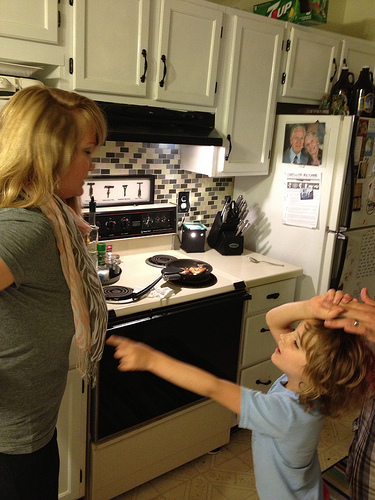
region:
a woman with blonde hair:
[0, 68, 110, 214]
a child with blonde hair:
[261, 293, 372, 423]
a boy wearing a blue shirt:
[251, 283, 361, 492]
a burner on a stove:
[142, 250, 180, 271]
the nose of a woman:
[84, 160, 97, 172]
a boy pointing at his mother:
[105, 283, 369, 413]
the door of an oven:
[93, 292, 253, 426]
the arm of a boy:
[105, 335, 243, 408]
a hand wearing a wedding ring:
[346, 288, 374, 338]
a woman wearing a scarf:
[4, 83, 116, 391]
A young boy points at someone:
[110, 287, 370, 498]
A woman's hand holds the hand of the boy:
[324, 288, 374, 342]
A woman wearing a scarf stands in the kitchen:
[0, 86, 108, 495]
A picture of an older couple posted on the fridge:
[282, 120, 325, 166]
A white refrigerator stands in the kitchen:
[279, 108, 372, 293]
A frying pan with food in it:
[164, 258, 211, 285]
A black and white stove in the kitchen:
[77, 209, 239, 497]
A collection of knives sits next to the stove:
[215, 196, 247, 255]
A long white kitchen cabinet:
[226, 14, 283, 173]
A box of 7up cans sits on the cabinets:
[250, 0, 325, 27]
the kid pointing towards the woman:
[114, 285, 361, 499]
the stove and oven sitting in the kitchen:
[84, 202, 244, 495]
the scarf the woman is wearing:
[37, 193, 114, 389]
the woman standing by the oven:
[7, 77, 86, 498]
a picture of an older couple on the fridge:
[282, 114, 328, 171]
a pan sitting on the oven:
[160, 254, 214, 288]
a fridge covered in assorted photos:
[271, 106, 371, 306]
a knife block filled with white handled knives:
[215, 195, 249, 258]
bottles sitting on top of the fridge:
[332, 60, 373, 119]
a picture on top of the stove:
[74, 173, 168, 204]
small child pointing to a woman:
[118, 282, 340, 495]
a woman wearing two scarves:
[4, 130, 137, 480]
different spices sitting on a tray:
[98, 247, 124, 289]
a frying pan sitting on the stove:
[157, 259, 228, 293]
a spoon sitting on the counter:
[250, 255, 286, 280]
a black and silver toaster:
[181, 203, 214, 253]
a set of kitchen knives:
[212, 190, 253, 262]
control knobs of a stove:
[106, 208, 178, 238]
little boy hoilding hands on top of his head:
[309, 284, 372, 338]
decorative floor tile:
[180, 450, 261, 495]